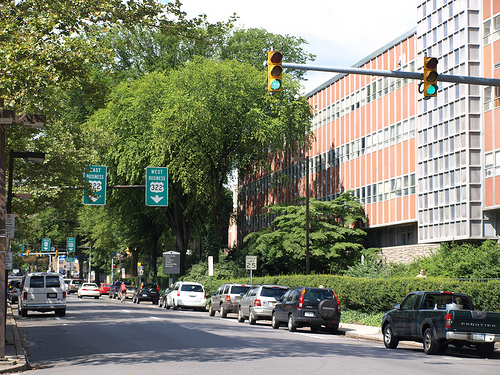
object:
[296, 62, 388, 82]
pole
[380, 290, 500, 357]
truck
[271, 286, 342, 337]
honda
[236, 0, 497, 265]
building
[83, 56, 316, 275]
trees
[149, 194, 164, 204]
arrow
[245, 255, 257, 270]
speed limit sign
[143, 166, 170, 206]
sign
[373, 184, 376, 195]
windows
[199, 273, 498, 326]
hedge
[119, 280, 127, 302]
person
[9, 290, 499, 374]
street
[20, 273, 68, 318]
van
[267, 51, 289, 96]
street sign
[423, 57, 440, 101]
street sign